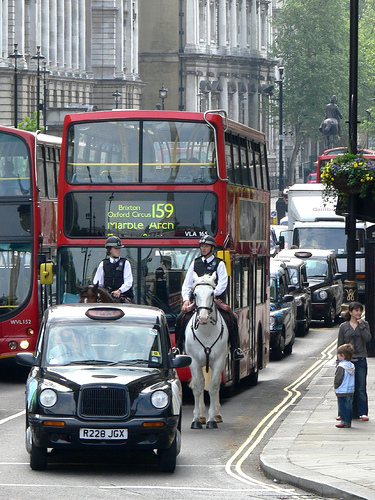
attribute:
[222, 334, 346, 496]
yellow lines — squiggly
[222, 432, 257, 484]
lines — painted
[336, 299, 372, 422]
woman — standing 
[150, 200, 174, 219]
number 159 — bus number 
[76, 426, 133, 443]
plate — license plate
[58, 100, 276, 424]
bus — double decker bus, red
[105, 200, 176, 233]
sign — electronic bus destination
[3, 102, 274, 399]
buses — red, double decker buses, driving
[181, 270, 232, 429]
horse — white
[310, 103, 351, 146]
statue — of man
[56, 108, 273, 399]
bus — red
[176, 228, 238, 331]
officer — police officer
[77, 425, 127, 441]
plate — white, license plate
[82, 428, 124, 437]
letters — black letters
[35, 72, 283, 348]
bus — red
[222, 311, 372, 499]
line — Wavy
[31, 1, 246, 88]
buildings — old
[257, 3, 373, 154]
leaves — green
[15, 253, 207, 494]
car — black 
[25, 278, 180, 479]
car — black 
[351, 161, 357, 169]
flower — yellow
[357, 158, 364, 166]
flower — yellow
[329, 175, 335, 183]
flower — yellow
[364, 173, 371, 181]
flower — yellow